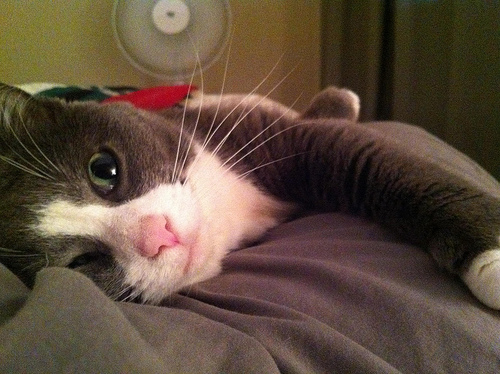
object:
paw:
[318, 86, 362, 122]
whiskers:
[0, 85, 60, 183]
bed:
[0, 83, 499, 374]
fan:
[104, 0, 237, 81]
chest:
[208, 168, 289, 243]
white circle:
[150, 0, 189, 36]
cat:
[0, 82, 499, 316]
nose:
[128, 213, 185, 259]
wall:
[3, 0, 323, 110]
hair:
[172, 28, 312, 223]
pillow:
[12, 82, 296, 118]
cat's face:
[0, 107, 219, 301]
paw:
[466, 249, 499, 312]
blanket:
[0, 121, 499, 374]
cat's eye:
[69, 142, 133, 270]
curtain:
[320, 0, 500, 182]